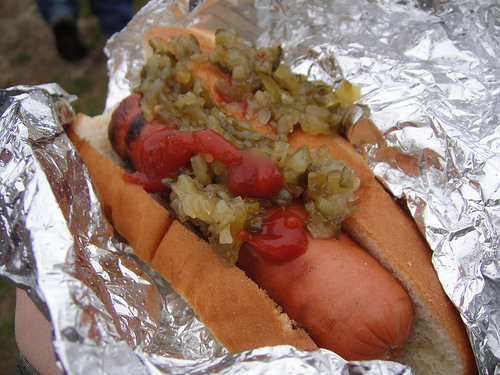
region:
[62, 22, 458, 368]
Hotdog is on a bun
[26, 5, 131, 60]
Person's shoe and pants are in the background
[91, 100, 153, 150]
Hotdog has a burn mark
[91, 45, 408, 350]
Hotdog has ketchup on it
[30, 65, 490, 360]
Hotdog is on top of tin foil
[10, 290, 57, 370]
Person's hand is holding the hot dog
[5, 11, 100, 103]
Grass patches and dirt are on the ground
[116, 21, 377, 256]
Radish is on top of hot dog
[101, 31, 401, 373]
Hotdog bun is light brown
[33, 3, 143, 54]
Person in the background's pants are blue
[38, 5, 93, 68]
black sole of man's shoe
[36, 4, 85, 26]
edge of blue jeans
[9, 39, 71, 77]
green spots on floor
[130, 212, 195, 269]
small groove in hot dog bun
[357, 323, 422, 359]
edge of pink hot dog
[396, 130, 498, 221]
wrinkles in shiny foil paper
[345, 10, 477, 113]
large piece of foil paper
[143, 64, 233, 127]
section of green relish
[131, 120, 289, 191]
red catsup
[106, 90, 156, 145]
burnt edge of hot dog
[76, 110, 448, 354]
a hot dog on a bun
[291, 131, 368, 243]
relish on a hot dog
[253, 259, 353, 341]
a grill mark on a hot dog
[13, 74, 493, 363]
hot dog on aluminum foil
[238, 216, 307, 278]
ketchup on hot dog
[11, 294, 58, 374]
hand holding a hot dog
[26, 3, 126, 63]
feet in background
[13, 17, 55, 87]
grass in the background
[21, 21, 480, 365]
it is daylight outside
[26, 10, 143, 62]
the shoes are a dark color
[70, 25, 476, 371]
hot dog in bun with toppings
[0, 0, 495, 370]
foil holding hot dog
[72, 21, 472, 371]
hot dog bun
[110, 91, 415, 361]
hot dog laying in bun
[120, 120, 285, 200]
large ketchup squirt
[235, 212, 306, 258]
small ketchup squirt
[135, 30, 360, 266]
diced onion hot dog topping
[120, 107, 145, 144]
burn spot on hot dog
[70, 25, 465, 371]
white bread under hot dog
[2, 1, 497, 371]
foil wrapped hot dog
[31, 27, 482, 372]
Hotdog on aluminum foil.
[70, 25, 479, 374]
Grilled wiener on a bun.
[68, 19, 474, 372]
Hotdog with relish and ketchup.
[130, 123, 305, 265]
Ketchup on a hotdog.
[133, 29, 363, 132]
Sweet relish on a hotdog.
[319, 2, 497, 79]
Aluminum foil with a hotdog.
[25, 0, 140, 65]
Person walking on the ground.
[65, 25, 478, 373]
Hotdog with condiments.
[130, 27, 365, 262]
Condiments on a hotdog.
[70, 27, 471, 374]
Hogdog served on aluminum foil.